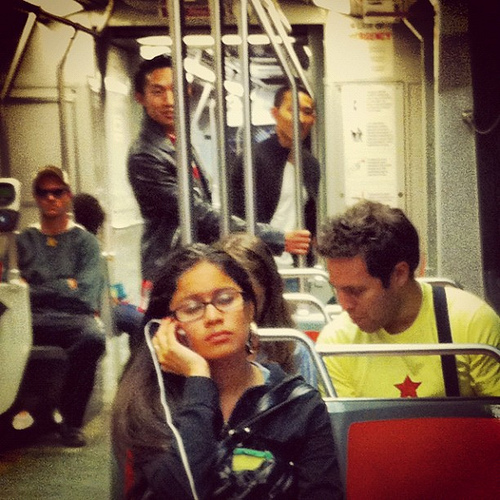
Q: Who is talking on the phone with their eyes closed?
A: Woman up front.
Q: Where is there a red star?
A: On yellow shirt.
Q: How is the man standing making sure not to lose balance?
A: Holding pole.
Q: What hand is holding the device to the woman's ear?
A: Right.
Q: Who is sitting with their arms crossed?
A: Man in sunglasses.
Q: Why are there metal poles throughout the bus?
A: Hold for balance.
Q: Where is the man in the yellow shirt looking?
A: Woman's lap.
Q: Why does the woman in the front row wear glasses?
A: To correct her vision.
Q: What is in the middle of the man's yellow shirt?
A: A red star.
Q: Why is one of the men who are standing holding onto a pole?
A: To help keep his balance.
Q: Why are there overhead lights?
A: To illuminate the train car.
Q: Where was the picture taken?
A: Inside a train car.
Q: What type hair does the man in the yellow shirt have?
A: Curly.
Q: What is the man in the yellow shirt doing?
A: Talking to the girl next to him.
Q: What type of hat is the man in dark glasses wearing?
A: Baseball hat.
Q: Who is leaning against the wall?
A: The man in the black jacket and white shirt.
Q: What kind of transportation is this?
A: Train.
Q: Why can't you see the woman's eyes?
A: They're closed.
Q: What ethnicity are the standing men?
A: Asian.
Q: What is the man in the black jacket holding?
A: Bar.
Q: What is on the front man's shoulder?
A: Strap.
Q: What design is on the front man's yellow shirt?
A: Star.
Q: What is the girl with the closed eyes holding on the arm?
A: Purse.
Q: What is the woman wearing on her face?
A: Eyeglasses.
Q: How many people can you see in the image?
A: Seven.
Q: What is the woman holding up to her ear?
A: A mobile phone.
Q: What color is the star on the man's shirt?
A: Red.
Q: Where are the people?
A: A subway train.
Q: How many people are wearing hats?
A: One.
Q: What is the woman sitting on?
A: A seat.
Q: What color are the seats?
A: Red.